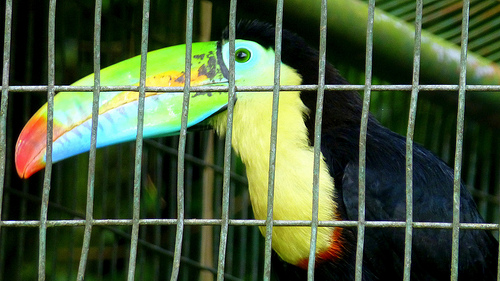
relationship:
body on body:
[223, 37, 494, 280] [211, 21, 497, 277]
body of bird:
[300, 63, 494, 280] [14, 20, 498, 279]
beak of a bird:
[12, 42, 224, 180] [14, 20, 498, 279]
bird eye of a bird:
[231, 47, 248, 62] [14, 20, 498, 279]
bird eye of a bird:
[231, 47, 248, 62] [51, 38, 416, 276]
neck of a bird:
[219, 40, 336, 245] [14, 20, 498, 279]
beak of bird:
[12, 42, 224, 180] [14, 20, 498, 279]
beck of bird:
[12, 27, 222, 184] [14, 20, 498, 279]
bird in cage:
[36, 52, 498, 273] [9, 4, 491, 265]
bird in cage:
[14, 20, 498, 279] [9, 4, 491, 265]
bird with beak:
[14, 20, 498, 279] [12, 42, 224, 182]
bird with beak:
[14, 20, 498, 279] [7, 30, 245, 185]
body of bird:
[223, 37, 494, 280] [14, 20, 498, 279]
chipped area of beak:
[195, 45, 231, 92] [12, 42, 224, 182]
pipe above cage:
[305, 1, 491, 127] [9, 4, 491, 265]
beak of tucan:
[12, 42, 224, 182] [20, 17, 498, 279]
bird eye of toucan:
[231, 47, 248, 62] [42, 35, 349, 182]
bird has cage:
[14, 20, 498, 279] [9, 4, 491, 265]